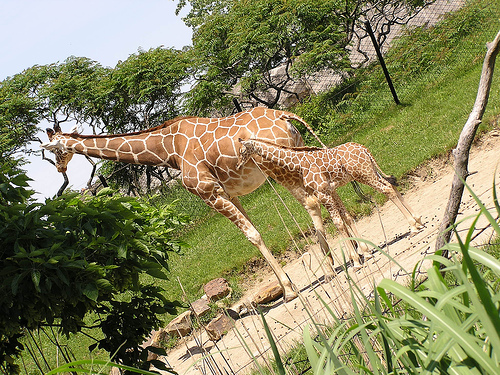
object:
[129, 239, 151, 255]
leaves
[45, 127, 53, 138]
horn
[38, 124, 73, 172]
head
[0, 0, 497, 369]
enclosure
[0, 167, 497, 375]
bushes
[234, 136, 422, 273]
giraffe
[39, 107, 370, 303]
giraffe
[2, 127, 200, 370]
tree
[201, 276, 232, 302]
rocks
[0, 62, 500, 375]
ground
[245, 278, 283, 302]
rocks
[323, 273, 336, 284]
feet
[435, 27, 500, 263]
stick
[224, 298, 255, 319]
rocks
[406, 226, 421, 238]
feet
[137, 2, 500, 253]
fence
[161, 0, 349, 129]
trees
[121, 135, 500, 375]
patch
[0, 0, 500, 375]
grass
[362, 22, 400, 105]
post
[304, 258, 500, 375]
grass